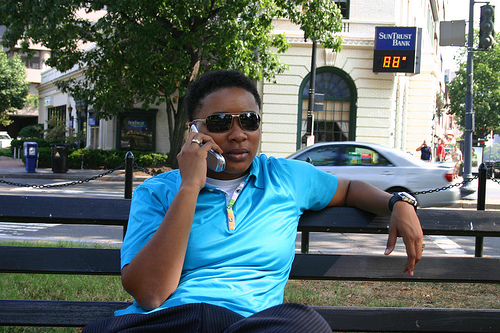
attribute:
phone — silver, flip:
[177, 123, 227, 175]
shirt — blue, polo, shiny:
[134, 153, 309, 300]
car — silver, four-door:
[267, 129, 462, 208]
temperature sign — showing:
[371, 22, 425, 77]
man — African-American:
[120, 73, 422, 331]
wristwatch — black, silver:
[391, 187, 423, 208]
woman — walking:
[109, 70, 424, 332]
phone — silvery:
[189, 123, 226, 172]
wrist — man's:
[378, 181, 441, 282]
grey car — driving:
[272, 136, 460, 203]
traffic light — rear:
[476, 1, 497, 50]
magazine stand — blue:
[23, 141, 35, 171]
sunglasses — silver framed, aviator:
[201, 108, 264, 137]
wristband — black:
[374, 182, 404, 217]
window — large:
[293, 64, 357, 146]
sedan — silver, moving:
[276, 130, 493, 206]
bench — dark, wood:
[49, 190, 96, 310]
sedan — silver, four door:
[281, 130, 471, 215]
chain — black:
[1, 164, 499, 196]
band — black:
[386, 190, 394, 220]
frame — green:
[298, 62, 358, 152]